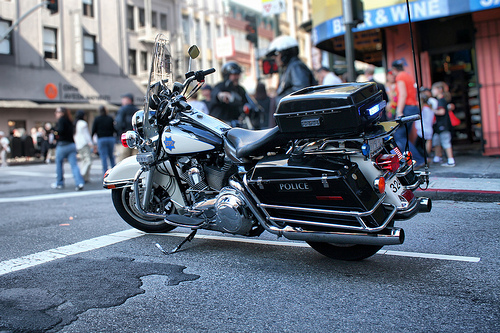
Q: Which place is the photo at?
A: It is at the road.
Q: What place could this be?
A: It is a road.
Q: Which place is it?
A: It is a road.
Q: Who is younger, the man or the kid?
A: The kid is younger than the man.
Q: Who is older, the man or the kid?
A: The man is older than the kid.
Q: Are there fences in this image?
A: No, there are no fences.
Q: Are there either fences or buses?
A: No, there are no fences or buses.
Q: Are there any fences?
A: No, there are no fences.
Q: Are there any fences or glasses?
A: No, there are no fences or glasses.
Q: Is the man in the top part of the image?
A: Yes, the man is in the top of the image.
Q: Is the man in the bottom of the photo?
A: No, the man is in the top of the image.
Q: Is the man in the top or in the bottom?
A: The man is in the top of the image.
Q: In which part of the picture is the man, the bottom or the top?
A: The man is in the top of the image.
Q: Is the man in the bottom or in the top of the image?
A: The man is in the top of the image.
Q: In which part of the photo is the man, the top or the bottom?
A: The man is in the top of the image.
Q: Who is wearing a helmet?
A: The man is wearing a helmet.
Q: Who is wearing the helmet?
A: The man is wearing a helmet.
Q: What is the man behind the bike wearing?
A: The man is wearing a helmet.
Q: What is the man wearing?
A: The man is wearing a helmet.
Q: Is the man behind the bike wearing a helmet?
A: Yes, the man is wearing a helmet.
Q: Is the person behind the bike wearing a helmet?
A: Yes, the man is wearing a helmet.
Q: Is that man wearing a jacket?
A: No, the man is wearing a helmet.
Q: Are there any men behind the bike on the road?
A: Yes, there is a man behind the bike.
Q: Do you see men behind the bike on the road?
A: Yes, there is a man behind the bike.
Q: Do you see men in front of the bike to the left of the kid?
A: No, the man is behind the bike.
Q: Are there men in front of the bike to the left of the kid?
A: No, the man is behind the bike.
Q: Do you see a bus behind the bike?
A: No, there is a man behind the bike.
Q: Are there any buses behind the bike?
A: No, there is a man behind the bike.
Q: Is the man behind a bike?
A: Yes, the man is behind a bike.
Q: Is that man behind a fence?
A: No, the man is behind a bike.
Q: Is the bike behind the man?
A: No, the man is behind the bike.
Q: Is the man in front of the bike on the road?
A: No, the man is behind the bike.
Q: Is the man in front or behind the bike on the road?
A: The man is behind the bike.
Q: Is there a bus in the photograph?
A: No, there are no buses.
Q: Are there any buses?
A: No, there are no buses.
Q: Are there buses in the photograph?
A: No, there are no buses.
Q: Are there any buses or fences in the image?
A: No, there are no buses or fences.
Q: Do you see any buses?
A: No, there are no buses.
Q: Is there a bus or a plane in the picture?
A: No, there are no buses or airplanes.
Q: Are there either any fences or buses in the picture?
A: No, there are no buses or fences.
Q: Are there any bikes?
A: Yes, there is a bike.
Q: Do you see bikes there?
A: Yes, there is a bike.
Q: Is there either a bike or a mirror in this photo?
A: Yes, there is a bike.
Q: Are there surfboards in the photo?
A: No, there are no surfboards.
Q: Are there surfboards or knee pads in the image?
A: No, there are no surfboards or knee pads.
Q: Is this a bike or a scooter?
A: This is a bike.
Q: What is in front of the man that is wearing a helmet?
A: The bike is in front of the man.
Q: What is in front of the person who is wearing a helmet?
A: The bike is in front of the man.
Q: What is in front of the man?
A: The bike is in front of the man.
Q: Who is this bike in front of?
A: The bike is in front of the man.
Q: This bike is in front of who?
A: The bike is in front of the man.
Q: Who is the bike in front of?
A: The bike is in front of the man.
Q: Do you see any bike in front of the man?
A: Yes, there is a bike in front of the man.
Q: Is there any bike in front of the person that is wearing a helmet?
A: Yes, there is a bike in front of the man.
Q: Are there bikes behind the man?
A: No, the bike is in front of the man.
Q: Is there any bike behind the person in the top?
A: No, the bike is in front of the man.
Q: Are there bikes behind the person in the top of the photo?
A: No, the bike is in front of the man.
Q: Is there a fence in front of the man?
A: No, there is a bike in front of the man.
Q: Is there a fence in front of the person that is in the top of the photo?
A: No, there is a bike in front of the man.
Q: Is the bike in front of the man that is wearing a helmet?
A: Yes, the bike is in front of the man.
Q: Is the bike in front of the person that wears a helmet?
A: Yes, the bike is in front of the man.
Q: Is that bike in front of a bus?
A: No, the bike is in front of the man.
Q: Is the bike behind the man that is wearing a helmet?
A: No, the bike is in front of the man.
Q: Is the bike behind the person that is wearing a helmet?
A: No, the bike is in front of the man.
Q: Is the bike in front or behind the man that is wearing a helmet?
A: The bike is in front of the man.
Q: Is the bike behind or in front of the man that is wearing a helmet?
A: The bike is in front of the man.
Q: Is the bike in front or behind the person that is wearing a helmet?
A: The bike is in front of the man.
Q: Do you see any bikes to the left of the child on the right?
A: Yes, there is a bike to the left of the child.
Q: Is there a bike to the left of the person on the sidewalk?
A: Yes, there is a bike to the left of the child.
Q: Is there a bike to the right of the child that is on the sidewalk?
A: No, the bike is to the left of the kid.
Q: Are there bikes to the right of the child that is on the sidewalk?
A: No, the bike is to the left of the kid.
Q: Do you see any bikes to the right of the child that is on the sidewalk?
A: No, the bike is to the left of the kid.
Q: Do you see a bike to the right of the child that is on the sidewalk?
A: No, the bike is to the left of the kid.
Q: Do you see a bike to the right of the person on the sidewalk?
A: No, the bike is to the left of the kid.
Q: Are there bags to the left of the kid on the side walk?
A: No, there is a bike to the left of the kid.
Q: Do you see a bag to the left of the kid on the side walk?
A: No, there is a bike to the left of the kid.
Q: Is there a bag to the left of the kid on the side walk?
A: No, there is a bike to the left of the kid.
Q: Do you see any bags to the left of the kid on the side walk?
A: No, there is a bike to the left of the kid.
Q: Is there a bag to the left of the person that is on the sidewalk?
A: No, there is a bike to the left of the kid.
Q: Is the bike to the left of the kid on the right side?
A: Yes, the bike is to the left of the kid.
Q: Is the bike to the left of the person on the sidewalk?
A: Yes, the bike is to the left of the kid.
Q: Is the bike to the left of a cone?
A: No, the bike is to the left of the kid.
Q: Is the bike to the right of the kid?
A: No, the bike is to the left of the kid.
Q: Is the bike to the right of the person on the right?
A: No, the bike is to the left of the kid.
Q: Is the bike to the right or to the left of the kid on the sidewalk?
A: The bike is to the left of the child.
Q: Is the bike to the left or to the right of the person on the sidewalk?
A: The bike is to the left of the child.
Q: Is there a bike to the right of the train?
A: Yes, there is a bike to the right of the train.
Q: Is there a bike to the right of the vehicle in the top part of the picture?
A: Yes, there is a bike to the right of the train.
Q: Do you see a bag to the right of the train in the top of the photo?
A: No, there is a bike to the right of the train.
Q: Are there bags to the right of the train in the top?
A: No, there is a bike to the right of the train.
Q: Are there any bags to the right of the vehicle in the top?
A: No, there is a bike to the right of the train.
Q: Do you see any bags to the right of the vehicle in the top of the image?
A: No, there is a bike to the right of the train.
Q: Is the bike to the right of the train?
A: Yes, the bike is to the right of the train.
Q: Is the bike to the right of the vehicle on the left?
A: Yes, the bike is to the right of the train.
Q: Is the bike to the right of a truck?
A: No, the bike is to the right of the train.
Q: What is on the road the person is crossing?
A: The bike is on the road.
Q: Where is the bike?
A: The bike is on the road.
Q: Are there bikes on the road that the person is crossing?
A: Yes, there is a bike on the road.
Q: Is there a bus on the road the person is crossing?
A: No, there is a bike on the road.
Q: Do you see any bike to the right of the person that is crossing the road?
A: Yes, there is a bike to the right of the person.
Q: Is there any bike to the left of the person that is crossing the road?
A: No, the bike is to the right of the person.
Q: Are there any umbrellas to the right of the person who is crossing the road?
A: No, there is a bike to the right of the person.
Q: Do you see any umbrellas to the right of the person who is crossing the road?
A: No, there is a bike to the right of the person.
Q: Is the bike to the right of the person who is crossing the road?
A: Yes, the bike is to the right of the person.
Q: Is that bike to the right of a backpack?
A: No, the bike is to the right of the person.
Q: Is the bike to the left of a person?
A: No, the bike is to the right of a person.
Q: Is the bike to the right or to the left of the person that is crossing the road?
A: The bike is to the right of the person.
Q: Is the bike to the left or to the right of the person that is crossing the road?
A: The bike is to the right of the person.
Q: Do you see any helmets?
A: Yes, there is a helmet.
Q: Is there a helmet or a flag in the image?
A: Yes, there is a helmet.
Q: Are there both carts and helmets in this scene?
A: No, there is a helmet but no carts.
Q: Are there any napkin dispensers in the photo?
A: No, there are no napkin dispensers.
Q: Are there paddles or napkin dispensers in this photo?
A: No, there are no napkin dispensers or paddles.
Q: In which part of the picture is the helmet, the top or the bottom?
A: The helmet is in the top of the image.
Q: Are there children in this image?
A: Yes, there is a child.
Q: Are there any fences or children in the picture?
A: Yes, there is a child.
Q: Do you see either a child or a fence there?
A: Yes, there is a child.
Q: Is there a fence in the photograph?
A: No, there are no fences.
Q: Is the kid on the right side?
A: Yes, the kid is on the right of the image.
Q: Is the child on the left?
A: No, the child is on the right of the image.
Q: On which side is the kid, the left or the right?
A: The kid is on the right of the image.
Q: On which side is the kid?
A: The kid is on the right of the image.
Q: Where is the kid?
A: The kid is on the sidewalk.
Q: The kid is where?
A: The kid is on the sidewalk.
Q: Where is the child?
A: The kid is on the sidewalk.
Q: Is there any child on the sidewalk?
A: Yes, there is a child on the sidewalk.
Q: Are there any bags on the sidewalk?
A: No, there is a child on the sidewalk.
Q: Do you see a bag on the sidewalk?
A: No, there is a child on the sidewalk.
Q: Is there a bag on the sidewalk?
A: No, there is a child on the sidewalk.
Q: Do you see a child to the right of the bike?
A: Yes, there is a child to the right of the bike.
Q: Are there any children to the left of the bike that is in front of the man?
A: No, the child is to the right of the bike.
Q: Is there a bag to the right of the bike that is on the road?
A: No, there is a child to the right of the bike.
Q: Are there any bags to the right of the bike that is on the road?
A: No, there is a child to the right of the bike.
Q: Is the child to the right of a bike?
A: Yes, the child is to the right of a bike.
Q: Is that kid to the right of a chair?
A: No, the kid is to the right of a bike.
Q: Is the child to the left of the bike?
A: No, the child is to the right of the bike.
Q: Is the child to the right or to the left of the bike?
A: The child is to the right of the bike.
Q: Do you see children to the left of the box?
A: No, the child is to the right of the box.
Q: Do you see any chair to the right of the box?
A: No, there is a child to the right of the box.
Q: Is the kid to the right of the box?
A: Yes, the kid is to the right of the box.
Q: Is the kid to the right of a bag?
A: No, the kid is to the right of the box.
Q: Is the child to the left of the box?
A: No, the child is to the right of the box.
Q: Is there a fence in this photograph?
A: No, there are no fences.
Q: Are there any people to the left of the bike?
A: Yes, there is a person to the left of the bike.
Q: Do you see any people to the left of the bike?
A: Yes, there is a person to the left of the bike.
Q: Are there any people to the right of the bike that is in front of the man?
A: No, the person is to the left of the bike.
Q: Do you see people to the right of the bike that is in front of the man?
A: No, the person is to the left of the bike.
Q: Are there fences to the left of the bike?
A: No, there is a person to the left of the bike.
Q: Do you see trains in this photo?
A: Yes, there is a train.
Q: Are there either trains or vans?
A: Yes, there is a train.